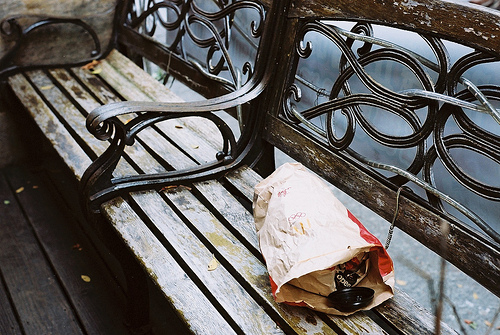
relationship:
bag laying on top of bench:
[253, 165, 398, 321] [22, 0, 499, 335]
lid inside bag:
[328, 286, 374, 314] [253, 165, 398, 321]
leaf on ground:
[78, 268, 94, 285] [3, 159, 127, 320]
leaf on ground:
[12, 176, 30, 201] [3, 159, 127, 320]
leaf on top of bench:
[79, 55, 107, 77] [22, 0, 499, 335]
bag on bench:
[253, 165, 398, 321] [22, 0, 499, 335]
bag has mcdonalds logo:
[253, 165, 398, 321] [346, 214, 396, 274]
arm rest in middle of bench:
[86, 77, 279, 198] [22, 0, 499, 335]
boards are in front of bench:
[17, 211, 82, 333] [22, 0, 499, 335]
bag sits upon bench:
[253, 165, 398, 321] [22, 0, 499, 335]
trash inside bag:
[301, 257, 376, 302] [253, 165, 398, 321]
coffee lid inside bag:
[328, 286, 374, 314] [253, 165, 398, 321]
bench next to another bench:
[83, 0, 500, 335] [147, 14, 499, 327]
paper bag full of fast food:
[253, 165, 398, 321] [301, 257, 376, 302]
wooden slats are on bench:
[147, 200, 233, 291] [22, 0, 499, 335]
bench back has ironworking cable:
[267, 14, 497, 140] [341, 25, 449, 74]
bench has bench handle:
[22, 0, 499, 335] [79, 94, 262, 123]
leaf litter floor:
[78, 272, 94, 282] [3, 159, 127, 320]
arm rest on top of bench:
[86, 77, 279, 198] [22, 0, 499, 335]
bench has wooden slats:
[22, 0, 499, 335] [147, 200, 233, 291]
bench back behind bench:
[267, 14, 497, 140] [22, 0, 499, 335]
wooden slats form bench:
[147, 200, 233, 291] [22, 0, 499, 335]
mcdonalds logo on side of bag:
[346, 214, 396, 274] [253, 165, 398, 321]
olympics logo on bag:
[285, 207, 315, 237] [253, 165, 398, 321]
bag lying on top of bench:
[253, 165, 398, 321] [22, 0, 499, 335]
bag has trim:
[253, 165, 398, 321] [269, 276, 286, 304]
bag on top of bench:
[253, 165, 398, 321] [22, 0, 499, 335]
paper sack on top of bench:
[253, 165, 398, 321] [22, 0, 499, 335]